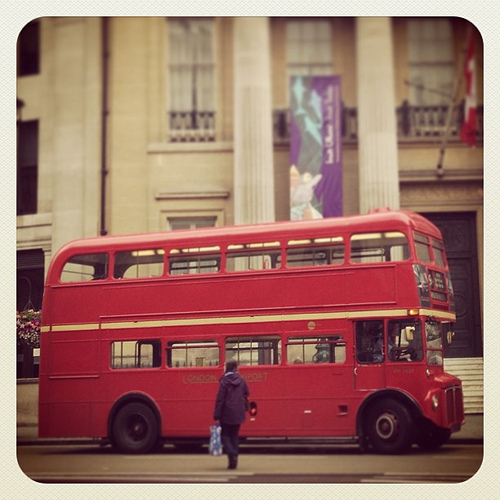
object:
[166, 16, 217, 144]
window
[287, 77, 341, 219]
flag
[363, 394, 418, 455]
wheel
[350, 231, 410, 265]
window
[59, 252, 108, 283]
window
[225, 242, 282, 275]
window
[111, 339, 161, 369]
window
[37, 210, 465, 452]
bus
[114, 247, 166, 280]
window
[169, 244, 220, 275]
window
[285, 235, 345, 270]
window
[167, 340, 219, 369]
window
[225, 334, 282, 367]
window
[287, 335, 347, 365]
window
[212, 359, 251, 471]
girl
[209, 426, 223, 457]
bag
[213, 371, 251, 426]
coat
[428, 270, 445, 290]
sign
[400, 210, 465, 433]
front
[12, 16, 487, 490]
foreground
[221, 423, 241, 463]
jeans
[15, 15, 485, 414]
building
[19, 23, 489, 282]
background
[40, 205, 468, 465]
view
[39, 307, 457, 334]
line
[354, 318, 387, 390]
door